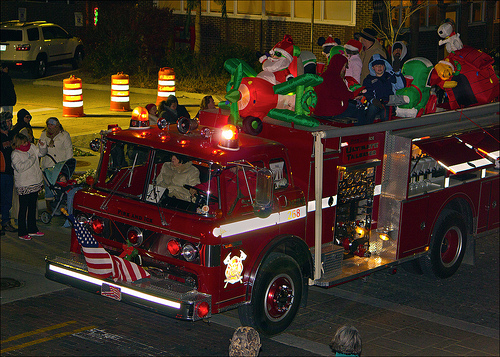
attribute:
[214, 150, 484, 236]
stripe — white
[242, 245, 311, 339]
tire — drivers side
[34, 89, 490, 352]
fire truck — red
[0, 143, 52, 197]
coat — white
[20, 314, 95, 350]
safety cones — orange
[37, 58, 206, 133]
construction barrel — reflective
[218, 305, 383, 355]
heads of two — spectators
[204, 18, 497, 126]
engine carrying toys — red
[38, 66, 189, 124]
cones on fire truck — orange, white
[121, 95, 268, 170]
lights on top — turned on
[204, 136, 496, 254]
white stripe — whiet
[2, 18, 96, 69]
utility vehicle — white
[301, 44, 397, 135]
hooded sweatshirt — red